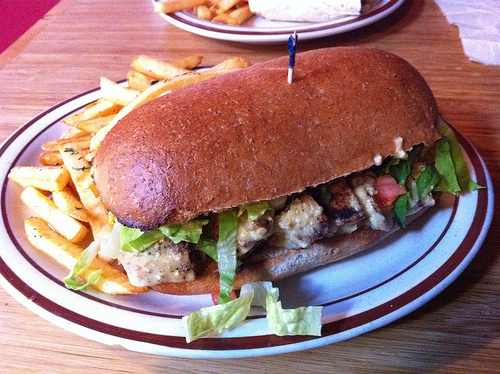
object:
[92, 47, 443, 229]
bun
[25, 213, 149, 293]
fries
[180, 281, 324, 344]
lettuce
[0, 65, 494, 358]
plate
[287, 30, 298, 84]
toothpick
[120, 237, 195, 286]
meat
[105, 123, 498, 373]
shadow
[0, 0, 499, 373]
table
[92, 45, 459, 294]
sandwich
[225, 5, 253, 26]
fries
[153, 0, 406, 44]
plate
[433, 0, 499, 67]
napkin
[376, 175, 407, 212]
tomato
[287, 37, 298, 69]
end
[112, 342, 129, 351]
chip